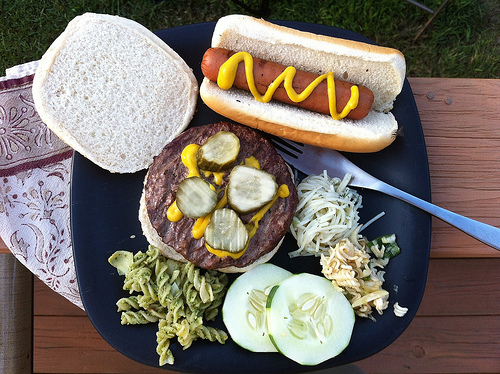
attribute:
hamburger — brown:
[146, 123, 298, 269]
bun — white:
[139, 162, 295, 269]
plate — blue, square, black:
[70, 22, 431, 374]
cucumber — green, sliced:
[266, 274, 354, 365]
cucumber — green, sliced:
[222, 263, 295, 353]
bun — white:
[200, 14, 405, 157]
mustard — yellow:
[216, 51, 358, 119]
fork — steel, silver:
[269, 138, 499, 250]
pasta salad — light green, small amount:
[109, 245, 228, 366]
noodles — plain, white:
[287, 170, 385, 256]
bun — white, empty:
[32, 13, 198, 174]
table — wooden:
[31, 78, 498, 373]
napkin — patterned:
[0, 59, 87, 312]